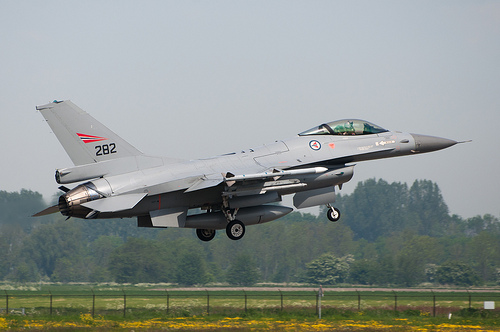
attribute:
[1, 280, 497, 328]
grasses — green, yellow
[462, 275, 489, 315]
sign — white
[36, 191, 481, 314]
trees — green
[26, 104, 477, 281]
jet — grey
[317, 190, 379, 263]
wheel — black, white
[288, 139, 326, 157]
logo — blue, white, red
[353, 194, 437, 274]
forest — green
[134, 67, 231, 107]
sky — hazy, cloudy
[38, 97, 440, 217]
airplane — light, dark, grey, jet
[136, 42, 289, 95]
sky — hazy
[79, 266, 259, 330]
lawn — grassy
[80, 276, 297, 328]
fence — black, metal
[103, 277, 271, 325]
fence — metal, black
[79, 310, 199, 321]
field — flowers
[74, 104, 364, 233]
plane — grey, jet, fighter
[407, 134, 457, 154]
nose — gray, pointed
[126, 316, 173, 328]
patch — yellow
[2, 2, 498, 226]
sky — hazy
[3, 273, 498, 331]
lawn — grassy